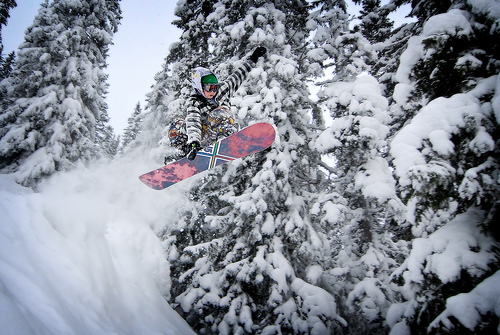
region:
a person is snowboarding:
[136, 45, 276, 190]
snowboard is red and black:
[138, 121, 274, 190]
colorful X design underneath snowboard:
[197, 140, 235, 170]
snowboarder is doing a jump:
[137, 45, 275, 190]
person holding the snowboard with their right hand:
[138, 45, 276, 190]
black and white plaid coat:
[183, 60, 257, 142]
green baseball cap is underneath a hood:
[201, 72, 222, 85]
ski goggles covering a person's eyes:
[200, 83, 221, 91]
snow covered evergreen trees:
[0, 0, 499, 333]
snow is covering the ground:
[1, 156, 196, 332]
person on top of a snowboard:
[137, 45, 276, 190]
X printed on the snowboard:
[196, 140, 234, 166]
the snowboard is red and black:
[138, 124, 282, 190]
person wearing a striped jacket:
[185, 56, 257, 141]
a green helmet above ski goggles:
[201, 73, 218, 83]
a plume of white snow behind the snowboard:
[0, 139, 202, 332]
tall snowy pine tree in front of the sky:
[0, 0, 122, 188]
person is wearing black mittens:
[250, 45, 266, 60]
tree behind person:
[127, 0, 333, 333]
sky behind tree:
[102, 0, 184, 151]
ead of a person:
[194, 71, 218, 99]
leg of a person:
[181, 109, 206, 151]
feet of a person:
[177, 135, 215, 173]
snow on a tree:
[378, 95, 445, 163]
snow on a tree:
[415, 211, 472, 281]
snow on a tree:
[25, 76, 55, 104]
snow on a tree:
[327, 51, 382, 113]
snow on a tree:
[242, 239, 314, 311]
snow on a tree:
[185, 246, 240, 303]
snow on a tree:
[312, 185, 363, 219]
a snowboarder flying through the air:
[137, 40, 279, 196]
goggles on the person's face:
[197, 81, 222, 93]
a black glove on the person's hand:
[250, 42, 270, 62]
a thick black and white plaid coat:
[184, 55, 258, 143]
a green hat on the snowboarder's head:
[201, 70, 222, 87]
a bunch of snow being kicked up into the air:
[35, 124, 194, 296]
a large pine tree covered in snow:
[0, 0, 126, 180]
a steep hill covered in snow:
[1, 174, 203, 334]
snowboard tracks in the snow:
[22, 229, 133, 334]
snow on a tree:
[95, 29, 119, 44]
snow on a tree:
[62, 102, 92, 139]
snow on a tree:
[15, 141, 59, 176]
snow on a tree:
[389, 92, 464, 183]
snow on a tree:
[402, 201, 489, 292]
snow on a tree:
[240, 238, 300, 292]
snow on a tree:
[333, 78, 383, 153]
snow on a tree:
[390, 43, 445, 108]